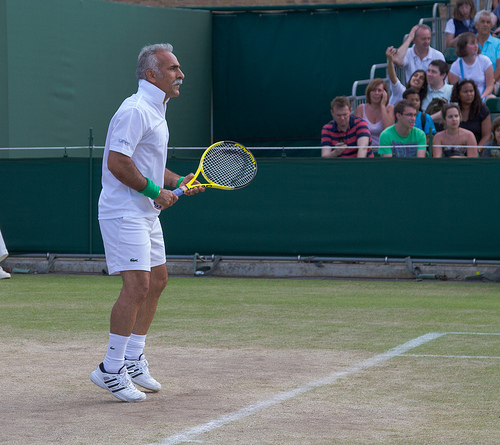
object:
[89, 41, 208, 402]
man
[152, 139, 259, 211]
racket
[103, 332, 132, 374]
white socks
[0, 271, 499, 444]
court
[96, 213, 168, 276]
sport shorts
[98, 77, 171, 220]
shirt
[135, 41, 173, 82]
hair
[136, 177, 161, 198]
arm band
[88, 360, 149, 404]
shoes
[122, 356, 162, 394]
shoes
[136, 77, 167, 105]
collar